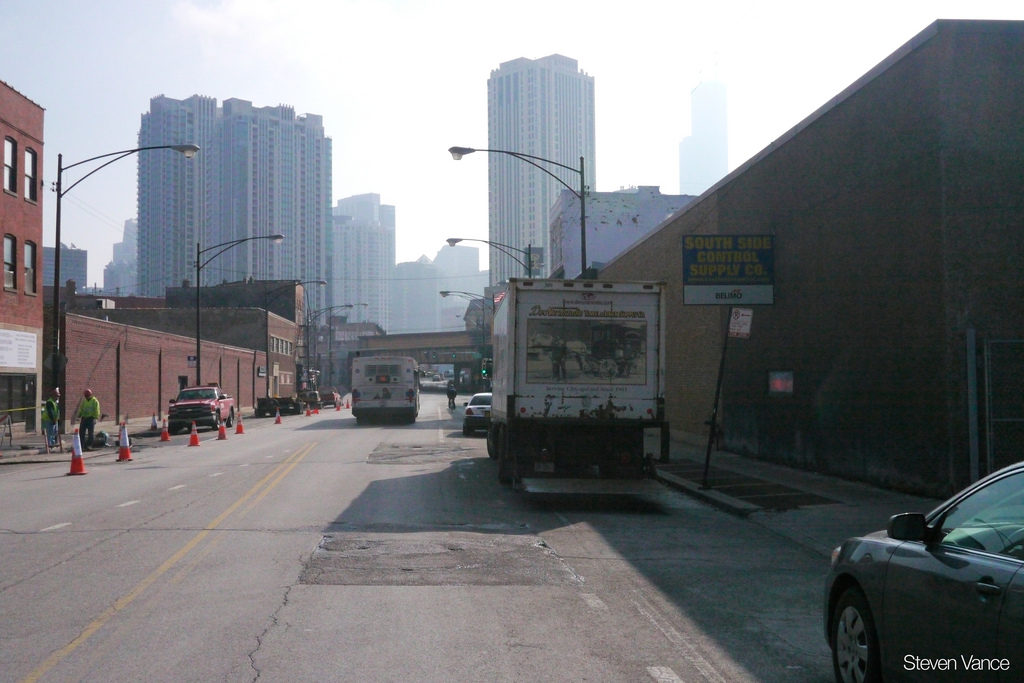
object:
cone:
[159, 418, 172, 442]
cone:
[216, 418, 230, 440]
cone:
[235, 412, 246, 434]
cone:
[273, 407, 282, 425]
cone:
[117, 422, 134, 462]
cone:
[65, 428, 89, 476]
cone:
[148, 412, 172, 442]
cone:
[187, 421, 200, 447]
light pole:
[195, 242, 200, 384]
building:
[446, 237, 529, 254]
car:
[463, 392, 493, 435]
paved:
[0, 378, 945, 683]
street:
[246, 526, 326, 683]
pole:
[195, 234, 286, 386]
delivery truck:
[485, 277, 668, 495]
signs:
[298, 191, 591, 586]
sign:
[687, 264, 770, 299]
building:
[597, 18, 1022, 501]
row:
[58, 281, 349, 476]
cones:
[113, 412, 157, 463]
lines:
[24, 441, 320, 681]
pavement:
[5, 537, 322, 683]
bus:
[358, 364, 408, 407]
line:
[98, 539, 204, 619]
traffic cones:
[66, 398, 351, 475]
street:
[0, 425, 830, 683]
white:
[490, 277, 666, 419]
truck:
[525, 318, 648, 385]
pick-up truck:
[169, 399, 216, 427]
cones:
[113, 412, 171, 462]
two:
[43, 389, 101, 450]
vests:
[80, 410, 94, 411]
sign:
[681, 234, 776, 307]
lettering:
[685, 237, 772, 283]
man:
[76, 388, 103, 449]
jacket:
[76, 396, 101, 419]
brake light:
[410, 388, 415, 403]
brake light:
[353, 389, 358, 403]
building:
[165, 281, 307, 390]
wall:
[58, 312, 266, 434]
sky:
[0, 1, 1022, 287]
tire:
[832, 589, 879, 680]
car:
[822, 461, 1024, 681]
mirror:
[887, 512, 926, 542]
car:
[169, 382, 237, 435]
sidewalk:
[644, 434, 943, 558]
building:
[487, 53, 597, 287]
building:
[135, 94, 330, 324]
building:
[331, 192, 397, 334]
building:
[397, 245, 488, 330]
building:
[548, 185, 698, 279]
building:
[679, 80, 729, 196]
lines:
[580, 593, 686, 682]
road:
[306, 584, 449, 681]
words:
[903, 654, 1010, 670]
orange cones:
[66, 418, 172, 475]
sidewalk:
[2, 425, 117, 465]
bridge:
[380, 332, 438, 364]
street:
[299, 442, 586, 586]